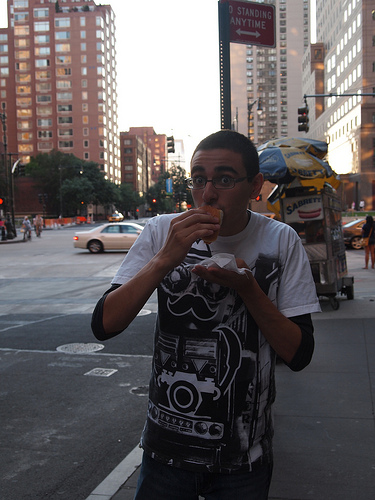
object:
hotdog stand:
[276, 180, 355, 309]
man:
[91, 130, 322, 499]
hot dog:
[195, 201, 224, 245]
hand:
[187, 257, 255, 291]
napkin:
[185, 250, 251, 274]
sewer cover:
[57, 340, 105, 358]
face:
[189, 149, 246, 226]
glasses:
[181, 171, 255, 192]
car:
[72, 220, 148, 256]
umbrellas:
[255, 133, 339, 205]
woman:
[356, 215, 375, 271]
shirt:
[360, 219, 375, 244]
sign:
[228, 0, 277, 50]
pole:
[217, 0, 234, 132]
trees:
[13, 151, 193, 228]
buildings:
[0, 1, 168, 218]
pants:
[363, 242, 375, 272]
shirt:
[109, 209, 320, 474]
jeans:
[133, 449, 273, 499]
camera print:
[157, 367, 222, 418]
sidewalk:
[0, 221, 375, 500]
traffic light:
[295, 100, 311, 134]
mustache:
[163, 291, 219, 322]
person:
[20, 214, 34, 240]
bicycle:
[19, 228, 33, 240]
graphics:
[139, 238, 281, 469]